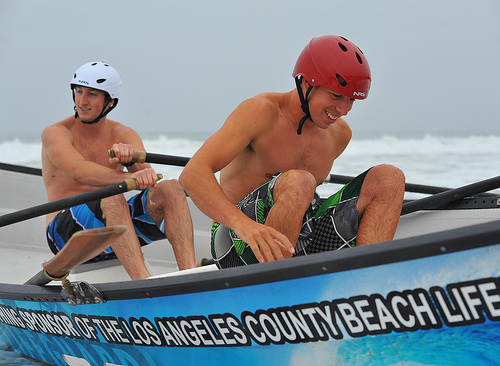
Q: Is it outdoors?
A: Yes, it is outdoors.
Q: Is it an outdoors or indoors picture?
A: It is outdoors.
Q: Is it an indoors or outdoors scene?
A: It is outdoors.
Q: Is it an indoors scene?
A: No, it is outdoors.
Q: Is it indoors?
A: No, it is outdoors.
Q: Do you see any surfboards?
A: No, there are no surfboards.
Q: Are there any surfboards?
A: No, there are no surfboards.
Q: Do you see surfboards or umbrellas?
A: No, there are no surfboards or umbrellas.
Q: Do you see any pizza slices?
A: No, there are no pizza slices.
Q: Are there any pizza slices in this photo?
A: No, there are no pizza slices.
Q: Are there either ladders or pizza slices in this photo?
A: No, there are no pizza slices or ladders.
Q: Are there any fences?
A: No, there are no fences.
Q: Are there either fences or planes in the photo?
A: No, there are no fences or planes.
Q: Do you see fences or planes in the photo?
A: No, there are no fences or planes.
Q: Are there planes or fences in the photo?
A: No, there are no fences or planes.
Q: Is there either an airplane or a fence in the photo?
A: No, there are no fences or airplanes.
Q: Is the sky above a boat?
A: Yes, the sky is above a boat.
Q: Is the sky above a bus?
A: No, the sky is above a boat.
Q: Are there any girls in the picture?
A: No, there are no girls.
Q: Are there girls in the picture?
A: No, there are no girls.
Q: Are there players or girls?
A: No, there are no girls or players.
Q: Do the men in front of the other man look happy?
A: Yes, the men are happy.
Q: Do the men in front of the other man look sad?
A: No, the men are happy.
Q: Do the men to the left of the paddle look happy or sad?
A: The men are happy.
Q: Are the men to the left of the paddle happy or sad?
A: The men are happy.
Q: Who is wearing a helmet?
A: The men are wearing a helmet.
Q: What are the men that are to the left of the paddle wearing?
A: The men are wearing a helmet.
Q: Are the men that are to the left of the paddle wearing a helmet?
A: Yes, the men are wearing a helmet.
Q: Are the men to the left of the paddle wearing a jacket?
A: No, the men are wearing a helmet.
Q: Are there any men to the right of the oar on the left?
A: Yes, there are men to the right of the oar.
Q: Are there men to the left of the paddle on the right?
A: Yes, there are men to the left of the paddle.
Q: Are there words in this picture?
A: Yes, there are words.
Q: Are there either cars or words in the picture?
A: Yes, there are words.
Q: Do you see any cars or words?
A: Yes, there are words.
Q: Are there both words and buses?
A: No, there are words but no buses.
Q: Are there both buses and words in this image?
A: No, there are words but no buses.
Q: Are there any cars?
A: No, there are no cars.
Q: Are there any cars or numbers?
A: No, there are no cars or numbers.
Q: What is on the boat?
A: The words are on the boat.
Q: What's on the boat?
A: The words are on the boat.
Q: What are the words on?
A: The words are on the boat.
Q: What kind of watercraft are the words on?
A: The words are on the boat.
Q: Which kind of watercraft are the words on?
A: The words are on the boat.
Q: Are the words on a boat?
A: Yes, the words are on a boat.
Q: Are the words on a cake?
A: No, the words are on a boat.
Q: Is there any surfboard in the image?
A: No, there are no surfboards.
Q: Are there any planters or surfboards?
A: No, there are no surfboards or planters.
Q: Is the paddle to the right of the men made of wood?
A: Yes, the paddle is made of wood.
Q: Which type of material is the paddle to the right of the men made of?
A: The paddle is made of wood.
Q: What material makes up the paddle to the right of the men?
A: The paddle is made of wood.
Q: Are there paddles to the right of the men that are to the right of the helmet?
A: Yes, there is a paddle to the right of the men.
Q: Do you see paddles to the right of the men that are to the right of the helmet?
A: Yes, there is a paddle to the right of the men.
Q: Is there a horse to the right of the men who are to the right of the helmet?
A: No, there is a paddle to the right of the men.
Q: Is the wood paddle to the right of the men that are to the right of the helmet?
A: Yes, the paddle is to the right of the men.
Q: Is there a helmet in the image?
A: Yes, there is a helmet.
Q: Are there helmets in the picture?
A: Yes, there is a helmet.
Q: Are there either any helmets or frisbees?
A: Yes, there is a helmet.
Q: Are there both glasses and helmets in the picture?
A: No, there is a helmet but no glasses.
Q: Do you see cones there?
A: No, there are no cones.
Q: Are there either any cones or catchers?
A: No, there are no cones or catchers.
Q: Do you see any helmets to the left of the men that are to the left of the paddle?
A: Yes, there is a helmet to the left of the men.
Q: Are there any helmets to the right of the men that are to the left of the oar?
A: No, the helmet is to the left of the men.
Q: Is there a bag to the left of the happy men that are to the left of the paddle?
A: No, there is a helmet to the left of the men.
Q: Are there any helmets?
A: Yes, there is a helmet.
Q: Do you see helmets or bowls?
A: Yes, there is a helmet.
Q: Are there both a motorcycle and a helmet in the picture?
A: No, there is a helmet but no motorcycles.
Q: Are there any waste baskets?
A: No, there are no waste baskets.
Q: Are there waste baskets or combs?
A: No, there are no waste baskets or combs.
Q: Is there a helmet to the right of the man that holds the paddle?
A: Yes, there is a helmet to the right of the man.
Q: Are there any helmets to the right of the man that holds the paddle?
A: Yes, there is a helmet to the right of the man.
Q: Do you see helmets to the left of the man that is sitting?
A: No, the helmet is to the right of the man.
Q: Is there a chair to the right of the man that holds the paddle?
A: No, there is a helmet to the right of the man.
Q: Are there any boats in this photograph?
A: Yes, there is a boat.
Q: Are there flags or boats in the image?
A: Yes, there is a boat.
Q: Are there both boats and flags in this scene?
A: No, there is a boat but no flags.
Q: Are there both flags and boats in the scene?
A: No, there is a boat but no flags.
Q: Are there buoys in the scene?
A: No, there are no buoys.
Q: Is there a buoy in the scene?
A: No, there are no buoys.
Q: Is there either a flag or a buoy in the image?
A: No, there are no buoys or flags.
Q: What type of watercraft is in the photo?
A: The watercraft is a boat.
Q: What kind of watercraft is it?
A: The watercraft is a boat.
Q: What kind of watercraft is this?
A: This is a boat.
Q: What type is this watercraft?
A: This is a boat.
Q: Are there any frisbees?
A: No, there are no frisbees.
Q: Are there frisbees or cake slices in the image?
A: No, there are no frisbees or cake slices.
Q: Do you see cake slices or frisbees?
A: No, there are no frisbees or cake slices.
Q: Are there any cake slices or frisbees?
A: No, there are no frisbees or cake slices.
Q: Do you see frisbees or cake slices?
A: No, there are no frisbees or cake slices.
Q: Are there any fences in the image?
A: No, there are no fences.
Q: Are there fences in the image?
A: No, there are no fences.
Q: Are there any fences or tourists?
A: No, there are no fences or tourists.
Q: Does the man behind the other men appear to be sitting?
A: Yes, the man is sitting.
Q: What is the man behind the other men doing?
A: The man is sitting.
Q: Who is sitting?
A: The man is sitting.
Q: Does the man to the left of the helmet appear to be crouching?
A: No, the man is sitting.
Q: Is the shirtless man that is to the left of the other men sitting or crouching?
A: The man is sitting.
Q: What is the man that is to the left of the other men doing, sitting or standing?
A: The man is sitting.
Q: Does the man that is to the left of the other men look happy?
A: Yes, the man is happy.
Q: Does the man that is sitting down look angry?
A: No, the man is happy.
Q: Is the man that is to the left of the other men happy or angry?
A: The man is happy.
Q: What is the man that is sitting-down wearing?
A: The man is wearing a helmet.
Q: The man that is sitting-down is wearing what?
A: The man is wearing a helmet.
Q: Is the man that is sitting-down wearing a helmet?
A: Yes, the man is wearing a helmet.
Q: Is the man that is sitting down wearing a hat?
A: No, the man is wearing a helmet.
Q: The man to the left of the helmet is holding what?
A: The man is holding the oar.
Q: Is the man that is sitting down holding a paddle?
A: Yes, the man is holding a paddle.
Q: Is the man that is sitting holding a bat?
A: No, the man is holding a paddle.